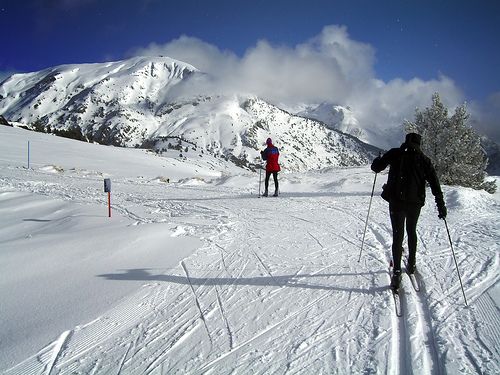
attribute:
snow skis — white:
[389, 254, 420, 318]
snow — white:
[2, 125, 496, 371]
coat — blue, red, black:
[261, 144, 281, 175]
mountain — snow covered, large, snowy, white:
[12, 48, 394, 175]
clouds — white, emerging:
[137, 27, 496, 149]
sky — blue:
[0, 3, 499, 148]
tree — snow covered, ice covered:
[401, 86, 488, 187]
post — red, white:
[101, 177, 119, 217]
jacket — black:
[376, 148, 441, 202]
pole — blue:
[24, 143, 35, 171]